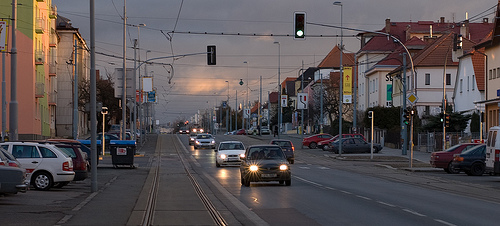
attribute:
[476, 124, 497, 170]
van — white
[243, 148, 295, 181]
car — red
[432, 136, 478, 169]
car parked — red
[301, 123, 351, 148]
car parked — red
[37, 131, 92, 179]
car parked — red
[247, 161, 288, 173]
headlights — dark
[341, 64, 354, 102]
sign — red, yellow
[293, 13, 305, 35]
traffic signal — green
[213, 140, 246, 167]
car — white, small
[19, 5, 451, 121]
sky — gray, stormy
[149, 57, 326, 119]
cloud — sun-lit, glowing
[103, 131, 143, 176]
bin — blue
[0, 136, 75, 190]
car — white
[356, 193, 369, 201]
line — white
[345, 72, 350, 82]
arrow — red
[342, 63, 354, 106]
sign — yellow and white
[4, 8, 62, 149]
building front — pink, green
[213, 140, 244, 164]
car — white